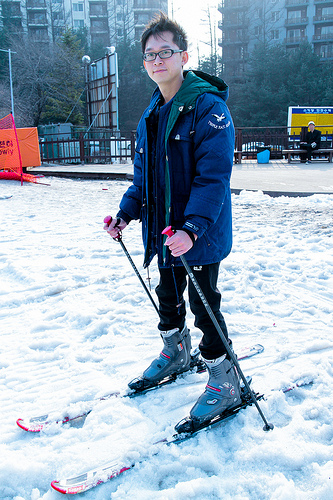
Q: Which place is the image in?
A: It is at the place.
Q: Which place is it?
A: It is a place.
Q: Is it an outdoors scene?
A: Yes, it is outdoors.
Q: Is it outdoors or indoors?
A: It is outdoors.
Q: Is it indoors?
A: No, it is outdoors.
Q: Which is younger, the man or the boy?
A: The boy is younger than the man.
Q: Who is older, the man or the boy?
A: The man is older than the boy.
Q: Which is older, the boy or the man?
A: The man is older than the boy.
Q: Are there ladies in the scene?
A: No, there are no ladies.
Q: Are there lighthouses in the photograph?
A: No, there are no lighthouses.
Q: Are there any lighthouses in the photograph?
A: No, there are no lighthouses.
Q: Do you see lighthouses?
A: No, there are no lighthouses.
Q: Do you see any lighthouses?
A: No, there are no lighthouses.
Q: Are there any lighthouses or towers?
A: No, there are no lighthouses or towers.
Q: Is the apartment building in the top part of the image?
A: Yes, the apartment building is in the top of the image.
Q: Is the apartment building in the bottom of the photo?
A: No, the apartment building is in the top of the image.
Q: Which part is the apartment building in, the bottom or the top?
A: The apartment building is in the top of the image.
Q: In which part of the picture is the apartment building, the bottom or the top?
A: The apartment building is in the top of the image.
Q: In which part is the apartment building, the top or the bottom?
A: The apartment building is in the top of the image.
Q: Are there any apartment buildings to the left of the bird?
A: Yes, there is an apartment building to the left of the bird.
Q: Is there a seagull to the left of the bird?
A: No, there is an apartment building to the left of the bird.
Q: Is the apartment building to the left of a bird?
A: Yes, the apartment building is to the left of a bird.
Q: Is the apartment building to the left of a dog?
A: No, the apartment building is to the left of a bird.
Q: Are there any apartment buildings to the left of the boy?
A: Yes, there is an apartment building to the left of the boy.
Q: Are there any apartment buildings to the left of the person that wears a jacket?
A: Yes, there is an apartment building to the left of the boy.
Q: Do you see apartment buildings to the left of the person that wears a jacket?
A: Yes, there is an apartment building to the left of the boy.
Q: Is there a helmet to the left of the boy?
A: No, there is an apartment building to the left of the boy.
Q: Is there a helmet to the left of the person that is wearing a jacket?
A: No, there is an apartment building to the left of the boy.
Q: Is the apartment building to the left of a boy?
A: Yes, the apartment building is to the left of a boy.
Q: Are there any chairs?
A: No, there are no chairs.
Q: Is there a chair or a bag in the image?
A: No, there are no chairs or bags.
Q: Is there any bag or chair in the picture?
A: No, there are no chairs or bags.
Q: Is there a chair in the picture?
A: No, there are no chairs.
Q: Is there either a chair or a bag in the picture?
A: No, there are no chairs or bags.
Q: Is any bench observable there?
A: Yes, there is a bench.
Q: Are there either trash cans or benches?
A: Yes, there is a bench.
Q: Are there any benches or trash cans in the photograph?
A: Yes, there is a bench.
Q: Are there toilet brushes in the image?
A: No, there are no toilet brushes.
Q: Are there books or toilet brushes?
A: No, there are no toilet brushes or books.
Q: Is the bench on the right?
A: Yes, the bench is on the right of the image.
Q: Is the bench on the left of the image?
A: No, the bench is on the right of the image.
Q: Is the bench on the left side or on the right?
A: The bench is on the right of the image.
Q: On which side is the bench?
A: The bench is on the right of the image.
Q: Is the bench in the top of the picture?
A: Yes, the bench is in the top of the image.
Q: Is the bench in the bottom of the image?
A: No, the bench is in the top of the image.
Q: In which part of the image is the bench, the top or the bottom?
A: The bench is in the top of the image.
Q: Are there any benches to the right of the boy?
A: Yes, there is a bench to the right of the boy.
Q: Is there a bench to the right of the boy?
A: Yes, there is a bench to the right of the boy.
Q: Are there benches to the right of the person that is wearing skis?
A: Yes, there is a bench to the right of the boy.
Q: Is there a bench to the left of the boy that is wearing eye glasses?
A: No, the bench is to the right of the boy.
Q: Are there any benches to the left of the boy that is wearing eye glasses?
A: No, the bench is to the right of the boy.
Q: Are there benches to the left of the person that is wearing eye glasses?
A: No, the bench is to the right of the boy.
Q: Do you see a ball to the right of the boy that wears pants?
A: No, there is a bench to the right of the boy.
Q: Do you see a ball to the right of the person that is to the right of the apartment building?
A: No, there is a bench to the right of the boy.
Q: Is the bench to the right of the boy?
A: Yes, the bench is to the right of the boy.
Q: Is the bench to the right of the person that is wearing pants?
A: Yes, the bench is to the right of the boy.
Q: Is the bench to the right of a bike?
A: No, the bench is to the right of the boy.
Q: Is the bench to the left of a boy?
A: No, the bench is to the right of a boy.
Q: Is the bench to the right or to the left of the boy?
A: The bench is to the right of the boy.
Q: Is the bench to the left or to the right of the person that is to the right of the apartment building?
A: The bench is to the right of the boy.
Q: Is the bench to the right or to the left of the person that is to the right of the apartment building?
A: The bench is to the right of the boy.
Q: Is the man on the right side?
A: Yes, the man is on the right of the image.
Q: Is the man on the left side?
A: No, the man is on the right of the image.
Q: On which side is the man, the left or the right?
A: The man is on the right of the image.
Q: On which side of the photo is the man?
A: The man is on the right of the image.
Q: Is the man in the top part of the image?
A: Yes, the man is in the top of the image.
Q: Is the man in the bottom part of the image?
A: No, the man is in the top of the image.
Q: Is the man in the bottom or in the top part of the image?
A: The man is in the top of the image.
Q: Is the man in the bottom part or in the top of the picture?
A: The man is in the top of the image.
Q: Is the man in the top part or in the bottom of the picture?
A: The man is in the top of the image.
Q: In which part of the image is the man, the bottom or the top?
A: The man is in the top of the image.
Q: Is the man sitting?
A: Yes, the man is sitting.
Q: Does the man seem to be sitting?
A: Yes, the man is sitting.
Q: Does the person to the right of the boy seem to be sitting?
A: Yes, the man is sitting.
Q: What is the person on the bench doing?
A: The man is sitting.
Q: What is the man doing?
A: The man is sitting.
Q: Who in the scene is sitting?
A: The man is sitting.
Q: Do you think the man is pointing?
A: No, the man is sitting.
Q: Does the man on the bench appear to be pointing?
A: No, the man is sitting.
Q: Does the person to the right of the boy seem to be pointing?
A: No, the man is sitting.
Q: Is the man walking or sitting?
A: The man is sitting.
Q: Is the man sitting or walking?
A: The man is sitting.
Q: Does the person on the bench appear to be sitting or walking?
A: The man is sitting.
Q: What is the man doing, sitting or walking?
A: The man is sitting.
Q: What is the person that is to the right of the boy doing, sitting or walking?
A: The man is sitting.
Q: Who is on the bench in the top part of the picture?
A: The man is on the bench.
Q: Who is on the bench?
A: The man is on the bench.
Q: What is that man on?
A: The man is on the bench.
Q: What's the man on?
A: The man is on the bench.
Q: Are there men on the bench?
A: Yes, there is a man on the bench.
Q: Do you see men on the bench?
A: Yes, there is a man on the bench.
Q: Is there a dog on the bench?
A: No, there is a man on the bench.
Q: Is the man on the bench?
A: Yes, the man is on the bench.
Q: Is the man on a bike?
A: No, the man is on the bench.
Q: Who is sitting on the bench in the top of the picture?
A: The man is sitting on the bench.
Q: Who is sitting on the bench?
A: The man is sitting on the bench.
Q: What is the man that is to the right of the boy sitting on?
A: The man is sitting on the bench.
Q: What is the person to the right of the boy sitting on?
A: The man is sitting on the bench.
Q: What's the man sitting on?
A: The man is sitting on the bench.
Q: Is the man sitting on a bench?
A: Yes, the man is sitting on a bench.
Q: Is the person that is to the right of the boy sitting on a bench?
A: Yes, the man is sitting on a bench.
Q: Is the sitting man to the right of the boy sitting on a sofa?
A: No, the man is sitting on a bench.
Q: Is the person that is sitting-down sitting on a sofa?
A: No, the man is sitting on a bench.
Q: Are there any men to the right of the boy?
A: Yes, there is a man to the right of the boy.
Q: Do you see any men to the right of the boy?
A: Yes, there is a man to the right of the boy.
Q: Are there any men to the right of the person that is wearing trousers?
A: Yes, there is a man to the right of the boy.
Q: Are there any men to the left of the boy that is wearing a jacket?
A: No, the man is to the right of the boy.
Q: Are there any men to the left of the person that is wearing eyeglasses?
A: No, the man is to the right of the boy.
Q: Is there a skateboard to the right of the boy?
A: No, there is a man to the right of the boy.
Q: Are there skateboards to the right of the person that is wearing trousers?
A: No, there is a man to the right of the boy.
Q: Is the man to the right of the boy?
A: Yes, the man is to the right of the boy.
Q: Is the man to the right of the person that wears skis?
A: Yes, the man is to the right of the boy.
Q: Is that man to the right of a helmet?
A: No, the man is to the right of the boy.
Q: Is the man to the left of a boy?
A: No, the man is to the right of a boy.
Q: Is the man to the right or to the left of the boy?
A: The man is to the right of the boy.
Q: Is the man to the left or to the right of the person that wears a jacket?
A: The man is to the right of the boy.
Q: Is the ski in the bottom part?
A: Yes, the ski is in the bottom of the image.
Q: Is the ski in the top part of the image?
A: No, the ski is in the bottom of the image.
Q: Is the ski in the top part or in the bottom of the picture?
A: The ski is in the bottom of the image.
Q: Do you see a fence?
A: Yes, there is a fence.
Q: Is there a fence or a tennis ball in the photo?
A: Yes, there is a fence.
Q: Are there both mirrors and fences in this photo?
A: No, there is a fence but no mirrors.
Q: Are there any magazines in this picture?
A: No, there are no magazines.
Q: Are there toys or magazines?
A: No, there are no magazines or toys.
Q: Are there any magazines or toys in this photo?
A: No, there are no magazines or toys.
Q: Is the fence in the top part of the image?
A: Yes, the fence is in the top of the image.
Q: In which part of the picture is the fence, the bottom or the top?
A: The fence is in the top of the image.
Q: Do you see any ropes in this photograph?
A: No, there are no ropes.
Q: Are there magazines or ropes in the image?
A: No, there are no ropes or magazines.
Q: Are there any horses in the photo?
A: No, there are no horses.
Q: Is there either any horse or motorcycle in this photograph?
A: No, there are no horses or motorcycles.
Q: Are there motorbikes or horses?
A: No, there are no horses or motorbikes.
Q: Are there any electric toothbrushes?
A: No, there are no electric toothbrushes.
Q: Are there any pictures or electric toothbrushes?
A: No, there are no electric toothbrushes or pictures.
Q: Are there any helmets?
A: No, there are no helmets.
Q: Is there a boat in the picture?
A: No, there are no boats.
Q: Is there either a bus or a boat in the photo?
A: No, there are no boats or buses.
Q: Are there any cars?
A: No, there are no cars.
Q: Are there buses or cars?
A: No, there are no cars or buses.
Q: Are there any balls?
A: No, there are no balls.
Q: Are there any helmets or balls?
A: No, there are no balls or helmets.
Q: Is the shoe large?
A: Yes, the shoe is large.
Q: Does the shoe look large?
A: Yes, the shoe is large.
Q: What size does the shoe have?
A: The shoe has large size.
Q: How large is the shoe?
A: The shoe is large.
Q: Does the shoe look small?
A: No, the shoe is large.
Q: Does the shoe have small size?
A: No, the shoe is large.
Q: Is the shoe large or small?
A: The shoe is large.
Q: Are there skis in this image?
A: Yes, there are skis.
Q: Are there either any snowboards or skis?
A: Yes, there are skis.